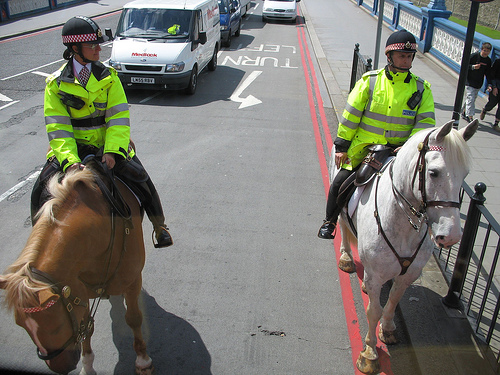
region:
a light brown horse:
[9, 165, 170, 373]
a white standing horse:
[328, 114, 480, 368]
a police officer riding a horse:
[319, 26, 469, 371]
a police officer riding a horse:
[5, 10, 174, 372]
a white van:
[108, 3, 223, 96]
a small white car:
[251, 0, 296, 25]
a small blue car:
[216, 1, 240, 49]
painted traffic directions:
[205, 39, 297, 114]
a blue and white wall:
[370, 3, 494, 107]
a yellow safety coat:
[332, 69, 437, 173]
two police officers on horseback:
[22, 6, 473, 351]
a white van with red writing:
[100, 0, 254, 115]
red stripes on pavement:
[291, 48, 362, 242]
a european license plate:
[123, 72, 159, 92]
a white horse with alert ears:
[308, 111, 485, 358]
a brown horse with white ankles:
[0, 136, 185, 373]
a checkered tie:
[71, 65, 101, 89]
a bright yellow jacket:
[321, 60, 446, 184]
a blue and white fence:
[370, 0, 484, 97]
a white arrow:
[223, 65, 270, 118]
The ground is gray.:
[206, 221, 286, 298]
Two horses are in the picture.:
[5, 113, 491, 370]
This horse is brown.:
[0, 145, 193, 368]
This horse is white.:
[309, 104, 486, 369]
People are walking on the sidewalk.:
[445, 25, 498, 152]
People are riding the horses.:
[5, 14, 493, 367]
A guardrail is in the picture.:
[453, 168, 498, 372]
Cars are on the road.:
[106, 0, 331, 102]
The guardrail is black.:
[458, 172, 498, 369]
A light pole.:
[441, 0, 486, 145]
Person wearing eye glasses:
[28, 12, 178, 254]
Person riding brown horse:
[23, 11, 175, 257]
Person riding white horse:
[312, 27, 439, 240]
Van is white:
[99, 0, 223, 104]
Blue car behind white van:
[219, 0, 245, 46]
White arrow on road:
[222, 70, 272, 112]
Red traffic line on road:
[285, 0, 392, 374]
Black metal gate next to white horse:
[346, 40, 498, 372]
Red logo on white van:
[130, 47, 160, 61]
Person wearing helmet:
[27, 12, 181, 255]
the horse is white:
[365, 117, 465, 371]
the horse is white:
[310, 154, 424, 348]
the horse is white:
[343, 228, 432, 370]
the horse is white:
[389, 209, 429, 369]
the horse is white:
[288, 129, 411, 365]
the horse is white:
[331, 130, 407, 290]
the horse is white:
[387, 148, 452, 334]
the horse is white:
[375, 109, 419, 339]